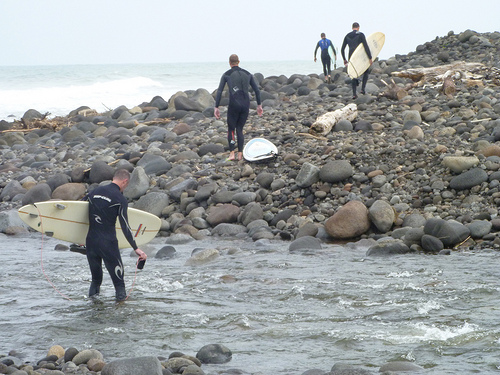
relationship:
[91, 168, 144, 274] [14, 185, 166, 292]
man holding board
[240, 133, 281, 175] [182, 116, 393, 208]
board on ground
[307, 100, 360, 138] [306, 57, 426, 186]
log washed up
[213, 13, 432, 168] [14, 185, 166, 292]
surfers holding board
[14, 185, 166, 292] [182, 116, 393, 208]
board on ground